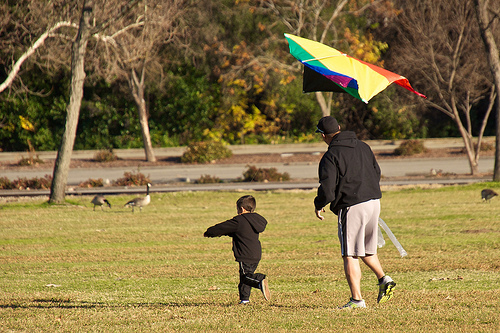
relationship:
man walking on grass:
[315, 113, 404, 309] [3, 184, 500, 331]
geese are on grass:
[89, 182, 153, 210] [3, 184, 500, 331]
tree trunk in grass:
[45, 4, 110, 205] [3, 184, 500, 331]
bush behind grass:
[184, 136, 239, 160] [3, 184, 500, 331]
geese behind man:
[89, 182, 153, 210] [315, 113, 404, 309]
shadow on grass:
[13, 279, 237, 312] [3, 184, 500, 331]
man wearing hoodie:
[315, 113, 404, 309] [313, 137, 381, 208]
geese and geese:
[89, 182, 153, 210] [89, 182, 153, 210]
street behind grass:
[6, 129, 500, 188] [3, 184, 500, 331]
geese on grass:
[89, 182, 153, 210] [3, 184, 500, 331]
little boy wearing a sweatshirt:
[201, 186, 278, 306] [209, 212, 266, 260]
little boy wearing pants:
[201, 186, 278, 306] [235, 262, 263, 298]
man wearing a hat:
[315, 113, 404, 309] [314, 118, 343, 132]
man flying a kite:
[315, 113, 404, 309] [281, 25, 433, 109]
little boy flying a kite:
[201, 186, 278, 306] [281, 25, 433, 109]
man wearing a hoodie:
[315, 113, 404, 309] [313, 137, 381, 208]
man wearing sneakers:
[315, 113, 404, 309] [342, 279, 396, 308]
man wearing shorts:
[315, 113, 404, 309] [337, 198, 378, 258]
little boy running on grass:
[201, 186, 278, 306] [3, 184, 500, 331]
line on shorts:
[339, 204, 353, 262] [337, 198, 378, 258]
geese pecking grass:
[89, 182, 153, 210] [3, 184, 500, 331]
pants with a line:
[235, 262, 263, 298] [239, 263, 262, 286]